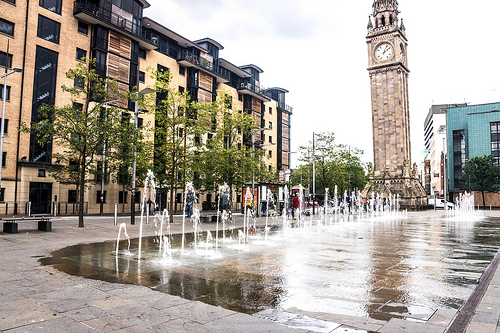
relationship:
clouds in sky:
[141, 0, 498, 180] [314, 0, 360, 51]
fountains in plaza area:
[113, 167, 400, 264] [6, 162, 484, 329]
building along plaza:
[2, 4, 287, 186] [2, 214, 497, 329]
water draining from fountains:
[38, 214, 500, 314] [76, 154, 472, 302]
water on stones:
[38, 214, 500, 314] [17, 185, 478, 328]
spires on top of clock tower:
[364, 12, 404, 33] [357, 0, 430, 210]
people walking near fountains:
[287, 191, 302, 218] [71, 147, 496, 328]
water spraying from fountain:
[134, 179, 482, 220] [106, 166, 483, 266]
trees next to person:
[126, 103, 283, 196] [259, 187, 318, 232]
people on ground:
[287, 191, 302, 218] [231, 197, 379, 277]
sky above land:
[143, 0, 498, 174] [157, 174, 478, 314]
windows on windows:
[266, 103, 272, 176] [451, 127, 467, 191]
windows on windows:
[266, 103, 272, 176] [1, 17, 14, 70]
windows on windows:
[266, 103, 272, 176] [490, 121, 499, 166]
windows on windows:
[266, 103, 272, 176] [206, 110, 218, 149]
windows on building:
[266, 103, 272, 176] [424, 101, 498, 208]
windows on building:
[266, 103, 272, 176] [2, 2, 290, 217]